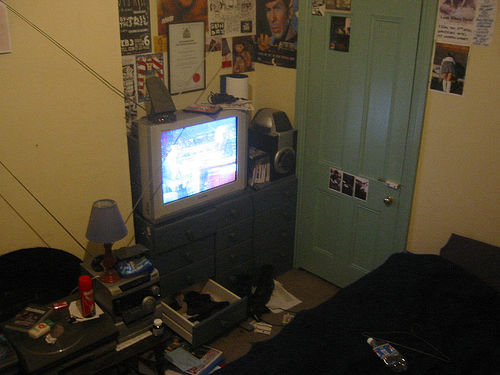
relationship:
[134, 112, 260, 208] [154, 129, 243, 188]
television has screen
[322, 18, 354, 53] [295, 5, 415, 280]
paper on door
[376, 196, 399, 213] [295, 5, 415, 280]
knob on door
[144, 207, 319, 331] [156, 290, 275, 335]
bureau has drawer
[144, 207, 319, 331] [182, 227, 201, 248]
bureau has knob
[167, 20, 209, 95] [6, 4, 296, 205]
document on wall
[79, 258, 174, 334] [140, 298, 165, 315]
stereo has knobs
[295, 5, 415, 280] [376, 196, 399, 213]
door has knob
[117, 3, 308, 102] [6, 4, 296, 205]
pictures on wall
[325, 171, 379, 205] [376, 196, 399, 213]
pictures near knob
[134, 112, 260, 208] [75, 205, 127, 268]
television behind lamp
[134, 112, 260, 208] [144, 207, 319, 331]
television sitting on bureau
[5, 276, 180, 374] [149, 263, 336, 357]
entertainment center on floor